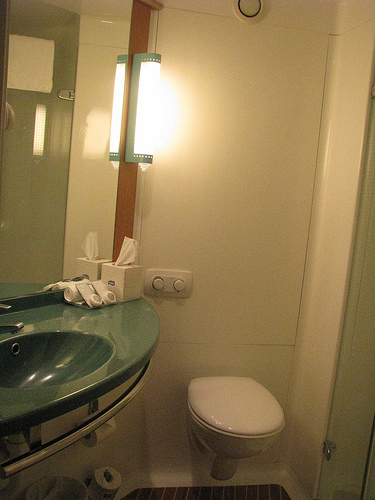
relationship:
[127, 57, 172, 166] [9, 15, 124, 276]
light on mirror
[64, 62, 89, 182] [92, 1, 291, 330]
knobs on wall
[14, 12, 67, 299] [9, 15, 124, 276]
door in mirror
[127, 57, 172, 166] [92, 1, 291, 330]
light on wall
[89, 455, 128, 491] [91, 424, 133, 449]
roll of toilet paper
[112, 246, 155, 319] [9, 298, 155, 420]
tissues on sink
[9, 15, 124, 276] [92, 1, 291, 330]
mirror on wall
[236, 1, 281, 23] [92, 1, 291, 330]
alarm on wall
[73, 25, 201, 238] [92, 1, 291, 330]
vanity on wall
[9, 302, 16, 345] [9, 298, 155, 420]
faucet on sink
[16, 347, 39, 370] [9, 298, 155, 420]
drain on sink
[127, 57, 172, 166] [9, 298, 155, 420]
light by sink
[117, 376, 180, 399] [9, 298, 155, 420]
rail under sink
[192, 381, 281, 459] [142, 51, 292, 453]
toilet on wall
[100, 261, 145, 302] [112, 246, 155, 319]
box of tissues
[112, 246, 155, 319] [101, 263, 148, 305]
tissues coming out of dispenser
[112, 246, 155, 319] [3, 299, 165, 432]
tissues on sink